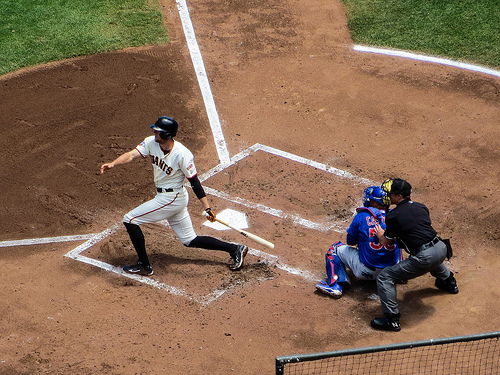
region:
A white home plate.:
[204, 203, 251, 232]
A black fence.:
[279, 332, 499, 372]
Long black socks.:
[124, 221, 239, 263]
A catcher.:
[312, 182, 396, 301]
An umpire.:
[374, 174, 459, 330]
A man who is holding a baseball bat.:
[97, 113, 277, 291]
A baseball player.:
[97, 107, 248, 275]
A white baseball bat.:
[207, 207, 275, 252]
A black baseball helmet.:
[151, 117, 178, 142]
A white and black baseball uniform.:
[121, 134, 235, 264]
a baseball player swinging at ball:
[99, 116, 275, 275]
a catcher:
[314, 184, 404, 301]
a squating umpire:
[368, 175, 457, 328]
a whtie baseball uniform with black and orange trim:
[122, 133, 199, 245]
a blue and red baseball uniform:
[322, 183, 394, 287]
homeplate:
[202, 205, 248, 237]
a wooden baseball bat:
[200, 211, 275, 251]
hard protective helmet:
[147, 118, 179, 140]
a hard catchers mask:
[362, 181, 392, 208]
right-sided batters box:
[190, 140, 383, 234]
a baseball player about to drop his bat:
[98, 115, 275, 276]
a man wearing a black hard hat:
[147, 114, 179, 146]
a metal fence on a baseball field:
[277, 333, 499, 373]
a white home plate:
[204, 201, 251, 232]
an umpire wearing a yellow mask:
[377, 175, 394, 205]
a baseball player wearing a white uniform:
[123, 135, 199, 247]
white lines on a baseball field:
[3, 1, 498, 306]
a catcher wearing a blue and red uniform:
[315, 184, 404, 300]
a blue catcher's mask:
[362, 182, 386, 210]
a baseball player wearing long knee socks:
[126, 223, 238, 263]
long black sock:
[187, 233, 241, 252]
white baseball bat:
[198, 205, 299, 262]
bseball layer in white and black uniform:
[99, 101, 229, 270]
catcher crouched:
[339, 164, 401, 301]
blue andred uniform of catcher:
[329, 198, 401, 295]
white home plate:
[206, 202, 272, 252]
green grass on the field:
[27, 15, 184, 74]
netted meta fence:
[263, 350, 381, 373]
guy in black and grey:
[382, 177, 469, 306]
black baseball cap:
[380, 166, 413, 195]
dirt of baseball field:
[2, 49, 497, 373]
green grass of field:
[352, 25, 499, 67]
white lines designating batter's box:
[66, 140, 393, 311]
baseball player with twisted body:
[100, 114, 247, 275]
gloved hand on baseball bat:
[200, 206, 275, 251]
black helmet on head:
[150, 115, 180, 140]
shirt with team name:
[139, 136, 191, 188]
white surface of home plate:
[203, 208, 248, 233]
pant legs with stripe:
[125, 191, 192, 242]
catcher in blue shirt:
[348, 187, 398, 269]